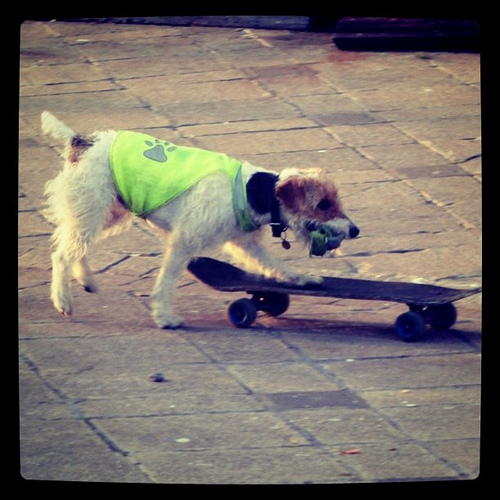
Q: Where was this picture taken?
A: A courtyard.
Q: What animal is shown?
A: A dog.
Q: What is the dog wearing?
A: A vest.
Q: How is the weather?
A: Sunny.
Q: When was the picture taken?
A: The afternoon.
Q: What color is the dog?
A: White.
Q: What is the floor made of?
A: Stone.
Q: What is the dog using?
A: A skateboard.